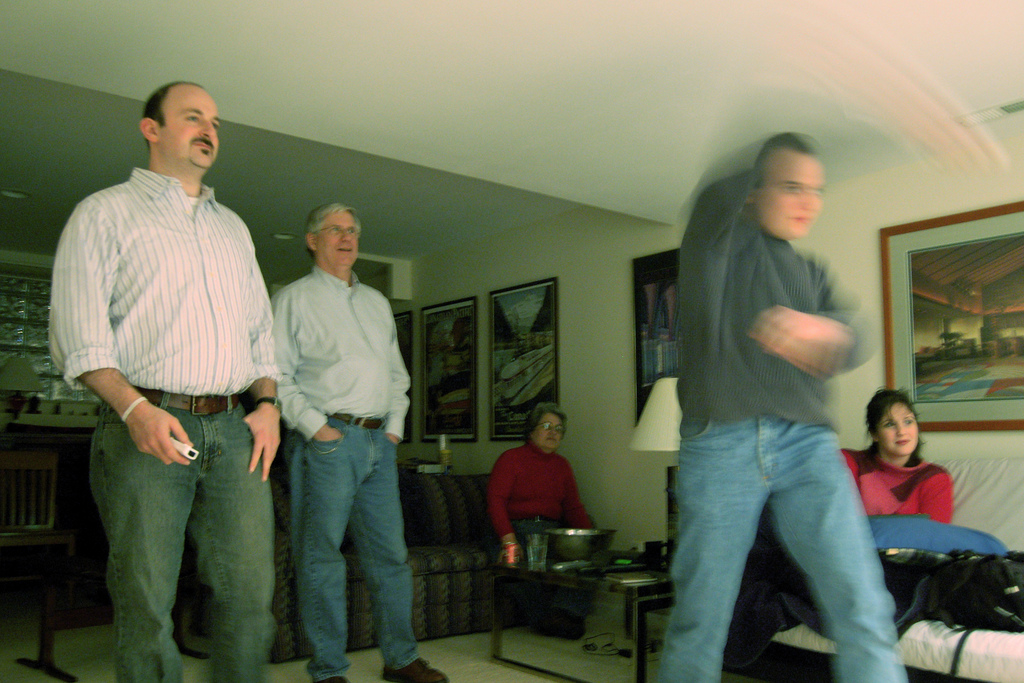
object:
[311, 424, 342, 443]
hand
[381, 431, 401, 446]
hand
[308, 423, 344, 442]
pocket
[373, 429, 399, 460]
pocket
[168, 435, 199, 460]
remote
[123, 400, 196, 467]
hand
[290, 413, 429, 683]
jeans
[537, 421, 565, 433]
glasses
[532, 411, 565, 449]
face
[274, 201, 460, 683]
man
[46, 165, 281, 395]
shirt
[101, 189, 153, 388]
stripe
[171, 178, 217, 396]
stripe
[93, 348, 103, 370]
stripe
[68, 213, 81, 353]
stripe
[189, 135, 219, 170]
goatee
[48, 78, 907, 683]
men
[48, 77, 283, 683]
man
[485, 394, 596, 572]
woman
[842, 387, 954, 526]
woman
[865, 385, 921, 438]
hair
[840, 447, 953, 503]
top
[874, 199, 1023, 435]
picture